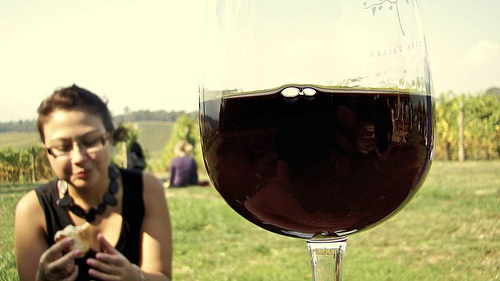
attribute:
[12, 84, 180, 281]
woman — sitting, eating, unfocused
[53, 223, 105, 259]
sandwich — eaten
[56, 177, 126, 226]
necklace — black, chunky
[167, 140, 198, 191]
hair — blonde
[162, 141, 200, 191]
woman — sitting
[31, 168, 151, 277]
top — black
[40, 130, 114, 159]
glasses — brown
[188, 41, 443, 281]
glass — transparent, full, focused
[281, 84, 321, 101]
bubbles — small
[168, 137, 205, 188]
person — unfocused, sitting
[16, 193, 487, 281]
grass — green, yellow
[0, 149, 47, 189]
corn — growing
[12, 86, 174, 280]
girl — sitting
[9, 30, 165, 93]
clouds — white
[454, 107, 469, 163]
post — brown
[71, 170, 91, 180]
lipstick — red